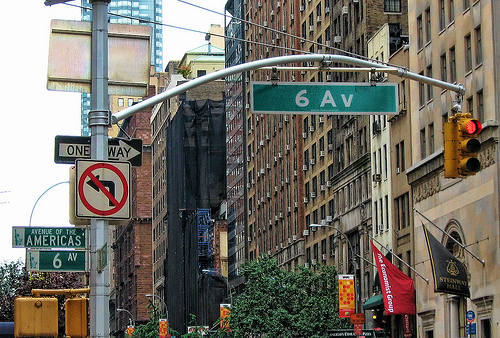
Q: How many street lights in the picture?
A: One.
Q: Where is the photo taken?
A: City.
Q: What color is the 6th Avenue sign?
A: Green and white.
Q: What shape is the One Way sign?
A: Rectangle.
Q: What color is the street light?
A: Red.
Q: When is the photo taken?
A: Daytime.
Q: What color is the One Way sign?
A: Black and white.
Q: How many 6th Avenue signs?
A: Two.